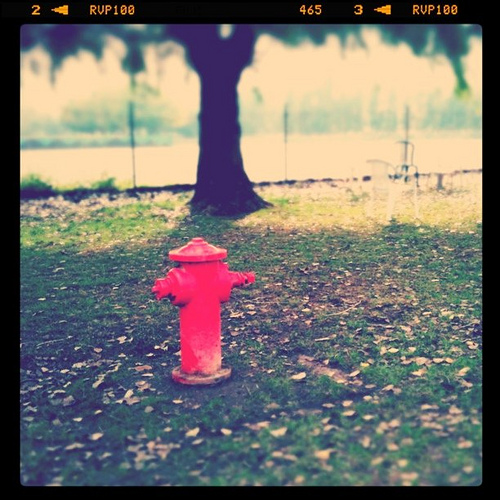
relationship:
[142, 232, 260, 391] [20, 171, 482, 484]
fire hydrant on grass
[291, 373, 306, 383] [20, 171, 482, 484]
leaf on grass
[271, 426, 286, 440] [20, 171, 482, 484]
leaf on grass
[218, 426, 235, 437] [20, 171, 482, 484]
leaf on grass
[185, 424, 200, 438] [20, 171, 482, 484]
leaf on grass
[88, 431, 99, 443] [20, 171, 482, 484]
leaf on grass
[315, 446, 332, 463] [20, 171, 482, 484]
leaf on grass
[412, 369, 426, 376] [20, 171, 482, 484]
leaf on grass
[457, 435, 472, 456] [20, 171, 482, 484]
leaf on grass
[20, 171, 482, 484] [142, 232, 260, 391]
grass surround fire hydrant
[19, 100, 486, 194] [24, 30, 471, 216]
blurred fence on background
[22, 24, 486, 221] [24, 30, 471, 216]
tree of background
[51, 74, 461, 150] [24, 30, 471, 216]
brush of background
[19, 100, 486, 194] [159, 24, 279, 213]
blurred fence behind tree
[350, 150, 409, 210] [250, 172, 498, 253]
white chair on grass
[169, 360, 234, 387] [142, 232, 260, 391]
muddy base of fire hydrant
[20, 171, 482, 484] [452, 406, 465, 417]
grass with leaf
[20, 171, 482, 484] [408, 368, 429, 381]
grass with leaf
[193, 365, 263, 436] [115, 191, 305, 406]
circle around hydrant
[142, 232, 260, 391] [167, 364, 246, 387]
fire hydrant on pedestal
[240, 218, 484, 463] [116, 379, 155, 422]
ground covered with leaves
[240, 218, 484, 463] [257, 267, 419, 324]
ground covered with leaves